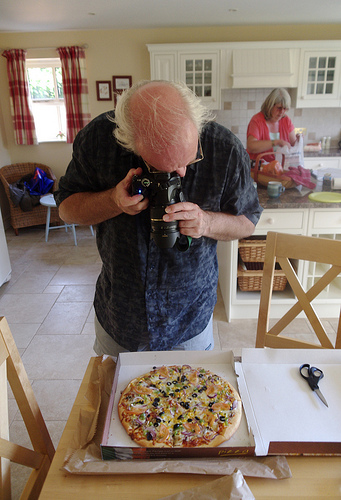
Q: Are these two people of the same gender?
A: No, they are both male and female.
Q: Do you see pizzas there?
A: Yes, there is a pizza.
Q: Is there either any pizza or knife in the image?
A: Yes, there is a pizza.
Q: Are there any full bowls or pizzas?
A: Yes, there is a full pizza.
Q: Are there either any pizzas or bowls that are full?
A: Yes, the pizza is full.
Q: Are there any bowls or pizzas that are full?
A: Yes, the pizza is full.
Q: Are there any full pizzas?
A: Yes, there is a full pizza.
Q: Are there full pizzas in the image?
A: Yes, there is a full pizza.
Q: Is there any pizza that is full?
A: Yes, there is a pizza that is full.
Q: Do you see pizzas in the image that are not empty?
A: Yes, there is an full pizza.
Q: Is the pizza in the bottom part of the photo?
A: Yes, the pizza is in the bottom of the image.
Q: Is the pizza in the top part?
A: No, the pizza is in the bottom of the image.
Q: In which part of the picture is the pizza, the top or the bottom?
A: The pizza is in the bottom of the image.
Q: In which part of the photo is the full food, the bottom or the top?
A: The pizza is in the bottom of the image.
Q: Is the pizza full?
A: Yes, the pizza is full.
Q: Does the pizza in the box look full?
A: Yes, the pizza is full.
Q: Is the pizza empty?
A: No, the pizza is full.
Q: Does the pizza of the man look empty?
A: No, the pizza is full.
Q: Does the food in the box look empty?
A: No, the pizza is full.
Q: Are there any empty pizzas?
A: No, there is a pizza but it is full.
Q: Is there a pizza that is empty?
A: No, there is a pizza but it is full.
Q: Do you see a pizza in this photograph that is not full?
A: No, there is a pizza but it is full.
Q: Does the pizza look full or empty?
A: The pizza is full.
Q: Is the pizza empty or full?
A: The pizza is full.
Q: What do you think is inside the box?
A: The pizza is inside the box.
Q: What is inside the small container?
A: The pizza is inside the box.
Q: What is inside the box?
A: The pizza is inside the box.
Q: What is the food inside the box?
A: The food is a pizza.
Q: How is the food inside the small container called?
A: The food is a pizza.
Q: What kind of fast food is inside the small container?
A: The food is a pizza.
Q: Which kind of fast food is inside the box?
A: The food is a pizza.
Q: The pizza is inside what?
A: The pizza is inside the box.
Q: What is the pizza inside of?
A: The pizza is inside the box.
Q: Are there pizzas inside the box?
A: Yes, there is a pizza inside the box.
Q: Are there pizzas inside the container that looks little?
A: Yes, there is a pizza inside the box.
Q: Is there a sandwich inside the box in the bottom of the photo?
A: No, there is a pizza inside the box.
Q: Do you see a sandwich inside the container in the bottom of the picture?
A: No, there is a pizza inside the box.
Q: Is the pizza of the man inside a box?
A: Yes, the pizza is inside a box.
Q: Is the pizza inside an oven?
A: No, the pizza is inside a box.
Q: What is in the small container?
A: The pizza is in the box.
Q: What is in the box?
A: The pizza is in the box.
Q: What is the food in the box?
A: The food is a pizza.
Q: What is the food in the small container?
A: The food is a pizza.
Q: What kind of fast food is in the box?
A: The food is a pizza.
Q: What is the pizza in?
A: The pizza is in the box.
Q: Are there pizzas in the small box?
A: Yes, there is a pizza in the box.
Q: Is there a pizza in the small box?
A: Yes, there is a pizza in the box.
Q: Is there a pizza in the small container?
A: Yes, there is a pizza in the box.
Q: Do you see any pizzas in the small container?
A: Yes, there is a pizza in the box.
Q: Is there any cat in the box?
A: No, there is a pizza in the box.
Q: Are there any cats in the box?
A: No, there is a pizza in the box.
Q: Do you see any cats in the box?
A: No, there is a pizza in the box.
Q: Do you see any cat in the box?
A: No, there is a pizza in the box.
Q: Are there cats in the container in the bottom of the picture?
A: No, there is a pizza in the box.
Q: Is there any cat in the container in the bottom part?
A: No, there is a pizza in the box.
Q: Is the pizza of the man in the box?
A: Yes, the pizza is in the box.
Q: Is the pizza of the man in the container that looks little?
A: Yes, the pizza is in the box.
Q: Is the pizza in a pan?
A: No, the pizza is in the box.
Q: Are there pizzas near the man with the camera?
A: Yes, there is a pizza near the man.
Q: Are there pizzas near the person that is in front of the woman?
A: Yes, there is a pizza near the man.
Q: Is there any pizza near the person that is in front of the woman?
A: Yes, there is a pizza near the man.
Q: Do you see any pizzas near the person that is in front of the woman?
A: Yes, there is a pizza near the man.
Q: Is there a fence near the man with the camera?
A: No, there is a pizza near the man.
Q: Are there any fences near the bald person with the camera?
A: No, there is a pizza near the man.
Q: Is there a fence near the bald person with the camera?
A: No, there is a pizza near the man.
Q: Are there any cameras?
A: Yes, there is a camera.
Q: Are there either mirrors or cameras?
A: Yes, there is a camera.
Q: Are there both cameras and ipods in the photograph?
A: No, there is a camera but no ipods.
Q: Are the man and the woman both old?
A: Yes, both the man and the woman are old.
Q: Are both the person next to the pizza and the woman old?
A: Yes, both the man and the woman are old.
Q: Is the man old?
A: Yes, the man is old.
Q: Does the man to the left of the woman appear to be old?
A: Yes, the man is old.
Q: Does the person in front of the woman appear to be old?
A: Yes, the man is old.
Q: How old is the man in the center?
A: The man is old.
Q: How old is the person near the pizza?
A: The man is old.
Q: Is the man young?
A: No, the man is old.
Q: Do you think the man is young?
A: No, the man is old.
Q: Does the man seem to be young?
A: No, the man is old.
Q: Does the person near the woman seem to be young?
A: No, the man is old.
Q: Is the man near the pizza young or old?
A: The man is old.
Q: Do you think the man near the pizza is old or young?
A: The man is old.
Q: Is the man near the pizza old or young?
A: The man is old.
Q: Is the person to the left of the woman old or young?
A: The man is old.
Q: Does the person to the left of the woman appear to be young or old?
A: The man is old.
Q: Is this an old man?
A: Yes, this is an old man.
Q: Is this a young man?
A: No, this is an old man.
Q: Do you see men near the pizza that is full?
A: Yes, there is a man near the pizza.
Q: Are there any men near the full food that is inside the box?
A: Yes, there is a man near the pizza.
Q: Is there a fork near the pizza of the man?
A: No, there is a man near the pizza.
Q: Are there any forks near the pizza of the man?
A: No, there is a man near the pizza.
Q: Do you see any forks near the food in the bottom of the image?
A: No, there is a man near the pizza.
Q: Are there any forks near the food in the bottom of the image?
A: No, there is a man near the pizza.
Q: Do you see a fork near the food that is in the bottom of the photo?
A: No, there is a man near the pizza.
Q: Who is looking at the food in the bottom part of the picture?
A: The man is looking at the pizza.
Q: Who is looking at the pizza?
A: The man is looking at the pizza.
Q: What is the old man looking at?
A: The man is looking at the pizza.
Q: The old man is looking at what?
A: The man is looking at the pizza.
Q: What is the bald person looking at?
A: The man is looking at the pizza.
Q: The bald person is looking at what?
A: The man is looking at the pizza.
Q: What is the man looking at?
A: The man is looking at the pizza.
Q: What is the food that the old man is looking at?
A: The food is a pizza.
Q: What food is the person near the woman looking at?
A: The man is looking at the pizza.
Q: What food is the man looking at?
A: The man is looking at the pizza.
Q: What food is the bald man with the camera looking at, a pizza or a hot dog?
A: The man is looking at a pizza.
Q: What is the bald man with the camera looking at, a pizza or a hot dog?
A: The man is looking at a pizza.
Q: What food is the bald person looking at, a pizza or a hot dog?
A: The man is looking at a pizza.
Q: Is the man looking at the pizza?
A: Yes, the man is looking at the pizza.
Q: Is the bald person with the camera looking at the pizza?
A: Yes, the man is looking at the pizza.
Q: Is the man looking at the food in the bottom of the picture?
A: Yes, the man is looking at the pizza.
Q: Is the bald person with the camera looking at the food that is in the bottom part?
A: Yes, the man is looking at the pizza.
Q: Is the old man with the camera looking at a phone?
A: No, the man is looking at the pizza.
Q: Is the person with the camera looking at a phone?
A: No, the man is looking at the pizza.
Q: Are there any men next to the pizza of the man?
A: Yes, there is a man next to the pizza.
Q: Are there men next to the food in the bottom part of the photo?
A: Yes, there is a man next to the pizza.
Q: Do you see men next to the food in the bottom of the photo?
A: Yes, there is a man next to the pizza.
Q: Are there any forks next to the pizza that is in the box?
A: No, there is a man next to the pizza.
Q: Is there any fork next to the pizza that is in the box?
A: No, there is a man next to the pizza.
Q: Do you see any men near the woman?
A: Yes, there is a man near the woman.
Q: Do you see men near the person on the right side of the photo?
A: Yes, there is a man near the woman.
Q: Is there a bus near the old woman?
A: No, there is a man near the woman.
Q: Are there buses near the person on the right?
A: No, there is a man near the woman.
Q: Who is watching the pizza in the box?
A: The man is watching the pizza.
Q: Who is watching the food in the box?
A: The man is watching the pizza.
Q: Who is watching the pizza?
A: The man is watching the pizza.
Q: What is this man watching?
A: The man is watching the pizza.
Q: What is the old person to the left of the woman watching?
A: The man is watching the pizza.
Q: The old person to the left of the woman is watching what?
A: The man is watching the pizza.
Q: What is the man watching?
A: The man is watching the pizza.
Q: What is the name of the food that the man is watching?
A: The food is a pizza.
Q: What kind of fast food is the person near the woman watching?
A: The man is watching the pizza.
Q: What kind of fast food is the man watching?
A: The man is watching the pizza.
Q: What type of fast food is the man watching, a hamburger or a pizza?
A: The man is watching a pizza.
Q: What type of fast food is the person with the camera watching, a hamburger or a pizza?
A: The man is watching a pizza.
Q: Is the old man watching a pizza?
A: Yes, the man is watching a pizza.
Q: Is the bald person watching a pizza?
A: Yes, the man is watching a pizza.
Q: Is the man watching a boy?
A: No, the man is watching a pizza.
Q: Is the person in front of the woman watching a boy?
A: No, the man is watching a pizza.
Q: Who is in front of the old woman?
A: The man is in front of the woman.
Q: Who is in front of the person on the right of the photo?
A: The man is in front of the woman.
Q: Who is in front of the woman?
A: The man is in front of the woman.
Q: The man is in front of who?
A: The man is in front of the woman.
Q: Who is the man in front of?
A: The man is in front of the woman.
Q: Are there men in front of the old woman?
A: Yes, there is a man in front of the woman.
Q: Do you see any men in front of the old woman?
A: Yes, there is a man in front of the woman.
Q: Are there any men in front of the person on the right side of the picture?
A: Yes, there is a man in front of the woman.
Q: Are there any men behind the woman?
A: No, the man is in front of the woman.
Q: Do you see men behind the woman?
A: No, the man is in front of the woman.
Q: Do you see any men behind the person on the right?
A: No, the man is in front of the woman.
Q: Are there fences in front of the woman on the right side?
A: No, there is a man in front of the woman.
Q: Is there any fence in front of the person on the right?
A: No, there is a man in front of the woman.